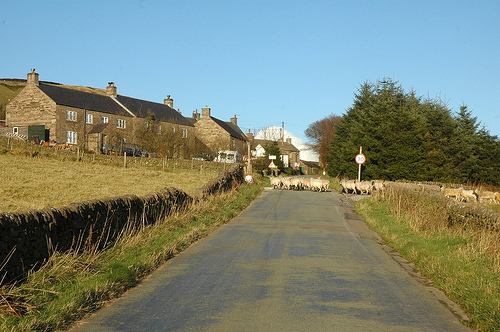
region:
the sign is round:
[347, 150, 371, 168]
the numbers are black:
[355, 153, 364, 164]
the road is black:
[192, 245, 234, 297]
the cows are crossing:
[262, 169, 425, 206]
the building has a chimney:
[20, 65, 45, 85]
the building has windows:
[67, 108, 129, 130]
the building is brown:
[23, 97, 48, 122]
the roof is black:
[61, 85, 108, 107]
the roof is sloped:
[55, 82, 109, 109]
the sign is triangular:
[262, 155, 282, 172]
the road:
[195, 119, 367, 315]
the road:
[140, 153, 288, 323]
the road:
[184, 196, 311, 313]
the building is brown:
[14, 47, 254, 197]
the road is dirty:
[46, 135, 473, 329]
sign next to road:
[350, 133, 372, 179]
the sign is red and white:
[347, 144, 377, 173]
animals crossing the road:
[253, 154, 492, 243]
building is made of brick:
[13, 70, 242, 177]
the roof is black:
[46, 72, 210, 132]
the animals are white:
[257, 163, 439, 213]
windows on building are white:
[57, 100, 123, 151]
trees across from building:
[322, 53, 497, 194]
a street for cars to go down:
[79, 178, 470, 330]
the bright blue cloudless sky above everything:
[2, 1, 489, 137]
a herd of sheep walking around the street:
[262, 173, 384, 200]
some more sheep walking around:
[442, 182, 498, 205]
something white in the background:
[252, 125, 313, 162]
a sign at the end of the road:
[351, 145, 366, 177]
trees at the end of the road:
[313, 86, 499, 191]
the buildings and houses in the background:
[1, 70, 302, 165]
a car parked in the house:
[212, 148, 239, 160]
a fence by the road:
[0, 186, 192, 258]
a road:
[148, 177, 355, 307]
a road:
[104, 167, 209, 254]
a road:
[214, 214, 355, 328]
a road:
[217, 180, 341, 284]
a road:
[252, 195, 312, 247]